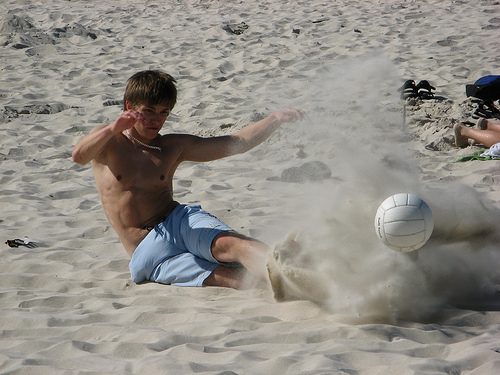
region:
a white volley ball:
[368, 193, 443, 253]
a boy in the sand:
[71, 70, 344, 325]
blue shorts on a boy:
[128, 206, 231, 291]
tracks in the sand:
[0, 243, 105, 348]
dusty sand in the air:
[281, 141, 387, 289]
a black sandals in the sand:
[397, 76, 439, 103]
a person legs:
[455, 115, 499, 151]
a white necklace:
[124, 132, 163, 158]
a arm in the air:
[197, 103, 310, 168]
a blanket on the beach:
[468, 141, 499, 161]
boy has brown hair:
[119, 49, 188, 130]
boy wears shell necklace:
[122, 123, 187, 162]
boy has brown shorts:
[129, 174, 231, 326]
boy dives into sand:
[87, 96, 370, 337]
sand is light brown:
[8, 302, 200, 373]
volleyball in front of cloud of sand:
[377, 201, 464, 262]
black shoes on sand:
[395, 75, 436, 116]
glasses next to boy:
[2, 227, 53, 260]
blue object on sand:
[452, 56, 498, 109]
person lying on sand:
[444, 89, 499, 131]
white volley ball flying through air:
[374, 193, 433, 251]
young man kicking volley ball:
[70, 70, 276, 295]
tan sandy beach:
[0, 0, 499, 372]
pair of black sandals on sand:
[396, 78, 436, 100]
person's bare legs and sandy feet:
[453, 117, 498, 148]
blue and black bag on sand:
[466, 73, 498, 102]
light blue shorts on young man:
[128, 203, 234, 285]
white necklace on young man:
[125, 130, 162, 152]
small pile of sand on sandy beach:
[1, 12, 33, 43]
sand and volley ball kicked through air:
[246, 55, 499, 319]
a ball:
[374, 195, 451, 262]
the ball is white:
[371, 190, 434, 254]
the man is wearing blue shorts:
[137, 237, 223, 284]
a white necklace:
[147, 139, 161, 156]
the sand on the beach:
[18, 309, 240, 369]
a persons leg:
[448, 115, 495, 150]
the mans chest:
[97, 160, 169, 227]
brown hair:
[127, 75, 170, 100]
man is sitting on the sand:
[70, 74, 337, 303]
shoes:
[398, 73, 441, 98]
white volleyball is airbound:
[373, 188, 438, 258]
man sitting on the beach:
[98, 86, 285, 296]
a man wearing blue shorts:
[116, 49, 292, 337]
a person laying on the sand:
[390, 65, 499, 165]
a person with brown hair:
[119, 61, 320, 372]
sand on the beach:
[67, 267, 156, 348]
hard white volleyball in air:
[381, 200, 436, 255]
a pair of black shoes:
[393, 80, 443, 114]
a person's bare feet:
[446, 106, 498, 158]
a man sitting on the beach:
[98, 60, 322, 333]